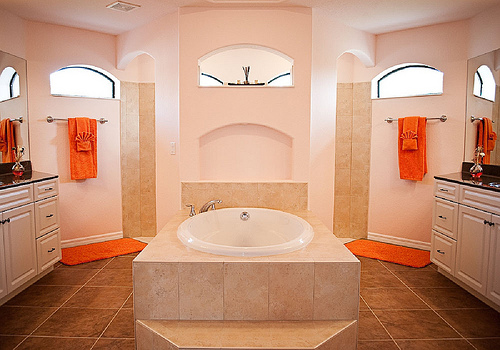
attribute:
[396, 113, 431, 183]
towels — orange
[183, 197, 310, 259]
tub — white, bath tub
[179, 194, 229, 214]
faucet — silver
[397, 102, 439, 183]
towel — orange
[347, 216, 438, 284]
mat — orange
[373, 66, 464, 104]
window — arched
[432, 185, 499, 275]
cabinets — white, wood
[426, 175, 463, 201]
drawer — white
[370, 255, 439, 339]
tiles — marble, tiled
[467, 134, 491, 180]
bottle — round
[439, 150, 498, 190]
countertop — shiny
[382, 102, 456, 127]
rack — silver, sivler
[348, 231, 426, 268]
rug — orange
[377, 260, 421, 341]
floor — brown, tiles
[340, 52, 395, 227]
doorway — arched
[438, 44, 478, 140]
wall — white